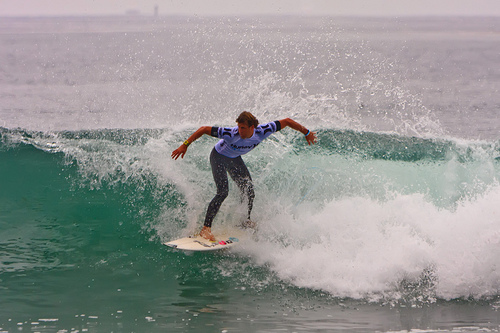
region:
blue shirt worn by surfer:
[214, 119, 279, 170]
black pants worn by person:
[202, 154, 264, 213]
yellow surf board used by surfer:
[164, 225, 293, 260]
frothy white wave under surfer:
[99, 139, 431, 271]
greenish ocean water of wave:
[11, 152, 132, 312]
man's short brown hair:
[229, 98, 268, 151]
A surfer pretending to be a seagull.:
[170, 109, 320, 244]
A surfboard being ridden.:
[160, 220, 255, 252]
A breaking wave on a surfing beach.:
[0, 121, 497, 305]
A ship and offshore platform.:
[122, 2, 162, 19]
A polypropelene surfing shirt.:
[207, 117, 284, 160]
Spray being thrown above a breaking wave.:
[10, 7, 453, 139]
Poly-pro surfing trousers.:
[202, 144, 257, 229]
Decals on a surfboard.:
[193, 235, 241, 250]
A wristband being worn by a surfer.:
[301, 128, 313, 139]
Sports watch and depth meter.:
[182, 138, 192, 147]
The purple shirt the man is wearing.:
[214, 122, 278, 157]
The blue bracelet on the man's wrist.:
[305, 129, 307, 133]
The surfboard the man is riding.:
[163, 229, 260, 251]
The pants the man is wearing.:
[201, 145, 256, 223]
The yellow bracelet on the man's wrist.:
[184, 139, 190, 146]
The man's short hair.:
[239, 108, 259, 125]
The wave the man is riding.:
[7, 123, 499, 297]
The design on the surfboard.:
[195, 235, 238, 248]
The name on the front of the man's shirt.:
[228, 142, 255, 150]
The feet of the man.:
[190, 221, 255, 241]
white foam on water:
[78, 242, 119, 274]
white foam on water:
[105, 273, 137, 315]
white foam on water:
[170, 252, 192, 304]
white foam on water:
[57, 295, 98, 327]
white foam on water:
[137, 299, 162, 324]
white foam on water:
[184, 289, 212, 330]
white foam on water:
[18, 296, 66, 331]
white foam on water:
[70, 305, 108, 326]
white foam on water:
[412, 289, 442, 310]